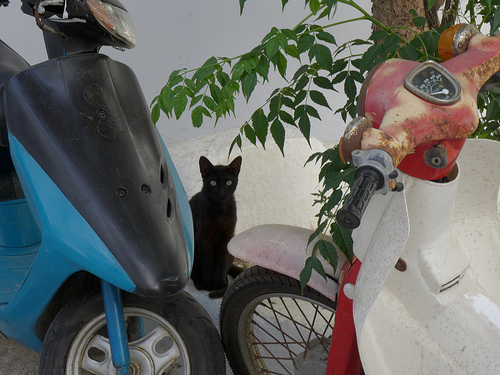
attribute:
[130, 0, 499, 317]
tree — small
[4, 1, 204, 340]
scooter — round, black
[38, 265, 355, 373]
tires — black, round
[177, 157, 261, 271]
cat — black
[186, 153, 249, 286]
cat — small, black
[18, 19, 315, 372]
motorbike — red, white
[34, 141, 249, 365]
motorbike — black, blue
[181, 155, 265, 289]
cat — black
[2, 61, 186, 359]
scooter — black, blue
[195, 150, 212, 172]
ear — black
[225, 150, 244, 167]
ear — black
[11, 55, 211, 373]
moped — blue and black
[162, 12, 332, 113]
leaves — green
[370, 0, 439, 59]
trunk — tree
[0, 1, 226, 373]
scooter — blue, black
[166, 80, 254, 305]
cat — two light colored cat 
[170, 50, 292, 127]
plant — green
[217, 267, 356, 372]
wheel — moped 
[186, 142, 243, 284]
cat — black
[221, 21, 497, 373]
scooter — red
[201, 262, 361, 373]
wheel — red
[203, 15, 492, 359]
motorbike — white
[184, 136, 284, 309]
motorbike — black, blue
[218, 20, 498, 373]
moped — white 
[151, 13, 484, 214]
tree — small 